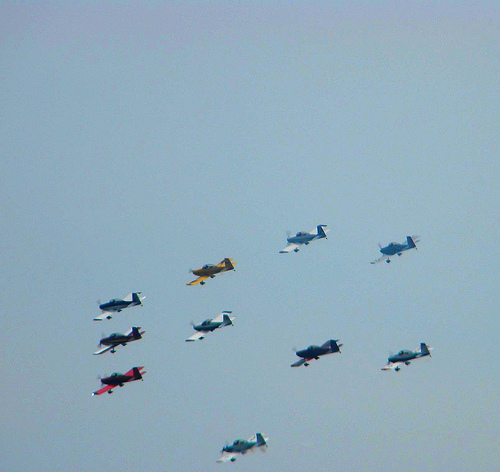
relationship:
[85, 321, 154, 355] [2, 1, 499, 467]
plane in sky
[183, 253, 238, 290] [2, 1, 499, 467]
plane in sky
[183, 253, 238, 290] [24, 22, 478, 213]
plane in sky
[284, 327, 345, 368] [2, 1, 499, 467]
plane in sky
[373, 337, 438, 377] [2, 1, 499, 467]
plane in sky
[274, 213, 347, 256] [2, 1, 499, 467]
plane in sky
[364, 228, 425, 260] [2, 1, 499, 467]
plane in sky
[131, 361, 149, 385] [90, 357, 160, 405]
tail of a plane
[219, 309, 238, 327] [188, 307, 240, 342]
tail of a plane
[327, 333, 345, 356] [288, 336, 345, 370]
tail of a plane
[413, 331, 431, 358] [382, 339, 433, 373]
tail plane of a plane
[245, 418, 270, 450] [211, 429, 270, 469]
tail plane of a plane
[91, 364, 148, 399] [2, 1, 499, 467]
plane flying in sky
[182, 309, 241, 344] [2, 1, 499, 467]
plane flying in sky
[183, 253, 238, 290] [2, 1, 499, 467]
plane flying in sky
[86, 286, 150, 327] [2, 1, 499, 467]
plane flying in sky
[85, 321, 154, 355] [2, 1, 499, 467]
plane flying in sky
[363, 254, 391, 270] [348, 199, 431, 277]
wings of plane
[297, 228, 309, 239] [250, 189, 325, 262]
window of plane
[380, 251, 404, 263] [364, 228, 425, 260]
wheels on plane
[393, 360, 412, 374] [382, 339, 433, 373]
wheels on plane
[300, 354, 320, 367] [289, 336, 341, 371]
wheels on plane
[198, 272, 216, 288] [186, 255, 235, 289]
wheels on plane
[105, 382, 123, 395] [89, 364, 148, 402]
wheels on plane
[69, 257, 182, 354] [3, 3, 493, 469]
plane doing tricks in air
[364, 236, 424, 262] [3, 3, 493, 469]
plane doing tricks in air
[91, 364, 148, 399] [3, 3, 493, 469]
plane doing tricks in air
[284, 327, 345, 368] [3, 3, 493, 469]
plane doing tricks in air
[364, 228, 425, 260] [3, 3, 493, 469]
plane doing tricks in air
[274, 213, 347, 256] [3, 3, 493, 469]
plane flying in air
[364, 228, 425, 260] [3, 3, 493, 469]
plane flying in air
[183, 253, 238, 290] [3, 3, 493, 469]
plane flying in air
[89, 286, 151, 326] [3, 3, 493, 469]
plane flying in air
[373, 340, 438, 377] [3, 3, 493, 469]
plane flying in air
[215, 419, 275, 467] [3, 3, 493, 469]
plane flying in air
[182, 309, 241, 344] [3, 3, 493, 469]
plane flying in air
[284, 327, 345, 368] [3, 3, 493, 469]
plane flying in air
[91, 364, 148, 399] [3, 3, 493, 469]
plane flying in air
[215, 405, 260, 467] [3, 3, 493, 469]
plane flying in air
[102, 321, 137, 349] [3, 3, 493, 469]
plane flying in air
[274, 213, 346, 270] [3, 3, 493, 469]
plane flying in air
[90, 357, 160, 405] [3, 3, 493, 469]
plane flying in air